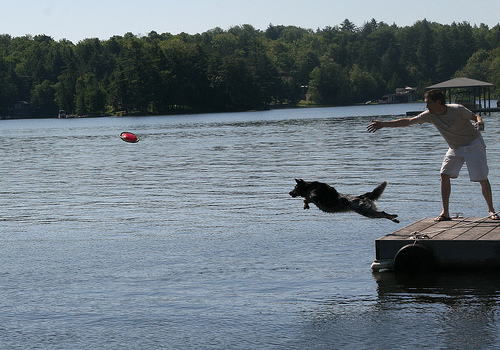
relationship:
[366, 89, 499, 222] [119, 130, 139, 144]
man throwing frisbee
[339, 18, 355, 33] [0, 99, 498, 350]
tree behind lake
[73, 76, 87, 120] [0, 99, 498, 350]
tree behind lake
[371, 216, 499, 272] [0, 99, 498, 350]
dock on lake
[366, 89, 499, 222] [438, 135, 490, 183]
man wearing a pair of shorts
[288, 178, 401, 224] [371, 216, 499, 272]
dog jumping off dock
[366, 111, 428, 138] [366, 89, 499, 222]
arm of man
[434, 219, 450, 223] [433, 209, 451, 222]
sandal on foot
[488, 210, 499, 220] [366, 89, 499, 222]
foot of man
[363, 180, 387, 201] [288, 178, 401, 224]
tail of dog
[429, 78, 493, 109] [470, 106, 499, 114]
gondela on pier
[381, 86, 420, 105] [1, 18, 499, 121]
house in woods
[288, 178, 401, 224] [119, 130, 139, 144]
dog jumping after frisbee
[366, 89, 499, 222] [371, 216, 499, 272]
man standing on dock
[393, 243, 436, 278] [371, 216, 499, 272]
tire on side of dock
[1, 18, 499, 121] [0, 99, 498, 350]
woods behind lake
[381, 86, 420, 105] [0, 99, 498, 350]
house behind lake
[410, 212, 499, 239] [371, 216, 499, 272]
rope on dock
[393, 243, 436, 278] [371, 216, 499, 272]
tire on dock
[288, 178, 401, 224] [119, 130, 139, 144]
dog chasing frisbee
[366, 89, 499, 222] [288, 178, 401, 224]
man playing with h dog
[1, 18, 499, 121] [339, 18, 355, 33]
woods are made of tree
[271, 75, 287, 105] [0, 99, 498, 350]
tree facing lake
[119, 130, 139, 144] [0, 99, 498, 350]
frisbee over lake